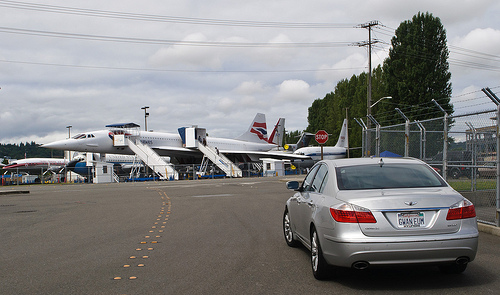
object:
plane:
[0, 158, 67, 170]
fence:
[365, 111, 497, 225]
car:
[281, 155, 479, 281]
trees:
[391, 12, 452, 145]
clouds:
[0, 36, 308, 112]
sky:
[6, 2, 499, 109]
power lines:
[1, 1, 360, 72]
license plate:
[394, 211, 431, 231]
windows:
[301, 167, 329, 193]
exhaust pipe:
[350, 260, 370, 273]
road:
[8, 185, 279, 288]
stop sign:
[315, 129, 329, 143]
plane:
[53, 111, 283, 181]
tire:
[310, 231, 336, 281]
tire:
[283, 210, 297, 249]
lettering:
[399, 217, 425, 228]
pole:
[358, 20, 380, 158]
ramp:
[124, 138, 180, 181]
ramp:
[198, 143, 243, 178]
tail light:
[333, 212, 375, 225]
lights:
[333, 206, 477, 224]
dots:
[113, 187, 172, 280]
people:
[197, 133, 220, 155]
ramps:
[129, 137, 240, 181]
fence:
[13, 161, 307, 184]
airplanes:
[8, 120, 283, 179]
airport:
[3, 102, 495, 185]